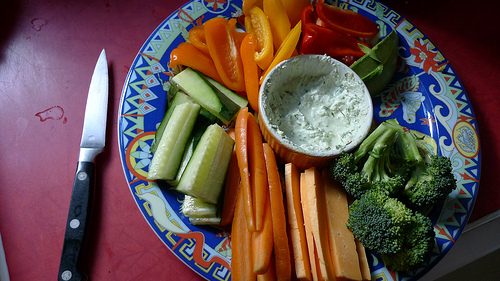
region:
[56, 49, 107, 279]
A knife on the plate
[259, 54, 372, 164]
Vegetable dip on the plate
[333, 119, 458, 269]
Broccoli next to the dip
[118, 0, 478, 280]
A paper plate on the table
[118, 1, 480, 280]
The plate is circular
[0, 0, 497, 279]
A table beneath the plate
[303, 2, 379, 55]
Red peppers on the plate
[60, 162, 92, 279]
A handle on the knife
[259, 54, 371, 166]
The cup of dip is almost empty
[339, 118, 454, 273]
Broccoli near the red peppers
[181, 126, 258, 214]
A piece of vegetable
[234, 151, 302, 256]
A piece of vegetable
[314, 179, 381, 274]
A piece of vegetable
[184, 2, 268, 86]
A piece of vegetable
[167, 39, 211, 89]
A piece of vegetable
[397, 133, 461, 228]
A piece of vegetable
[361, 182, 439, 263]
A piece of vegetable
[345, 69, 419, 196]
A piece of vegetable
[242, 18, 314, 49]
A piece of vegetable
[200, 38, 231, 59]
the pepper is orange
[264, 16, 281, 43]
the pepper is yellow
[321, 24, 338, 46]
the pepper is red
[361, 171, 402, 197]
the broccoli is green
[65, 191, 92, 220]
the handle is black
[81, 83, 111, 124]
the knife is silver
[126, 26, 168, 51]
the plate is on the table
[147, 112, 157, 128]
the plate is blue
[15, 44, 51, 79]
the table is red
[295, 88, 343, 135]
the dressing is white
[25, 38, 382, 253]
this is a snack food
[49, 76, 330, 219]
this is an appetizer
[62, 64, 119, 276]
this is a knife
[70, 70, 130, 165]
the blade is silver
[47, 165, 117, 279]
the handle is black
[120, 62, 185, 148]
the plate is multicolored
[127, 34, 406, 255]
the vegetables are sliced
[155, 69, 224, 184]
these are cucumbers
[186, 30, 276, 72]
these are peppers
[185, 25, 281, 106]
the pepper slices are orange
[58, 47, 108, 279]
the knife is sharp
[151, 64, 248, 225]
the cucumbers are green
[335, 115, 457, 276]
the broccoli is green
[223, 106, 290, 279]
the pile of cut carrots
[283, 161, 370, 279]
the pile of cut cheese